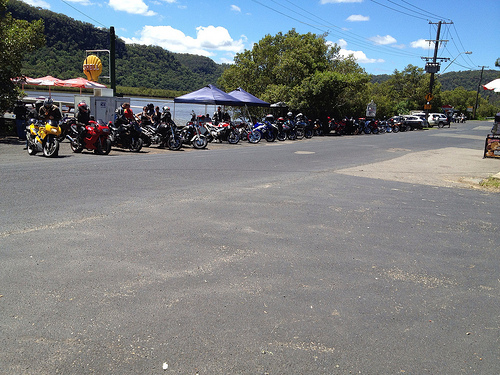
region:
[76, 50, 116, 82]
shell gas station shell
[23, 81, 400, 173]
row of motorcycles on the street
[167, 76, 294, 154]
blue tarps providing shade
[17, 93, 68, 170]
yellow motorcycle with a rider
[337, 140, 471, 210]
asphalt with two colors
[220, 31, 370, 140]
green tree behind a motorcycle line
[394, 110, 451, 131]
vehicles parked on the street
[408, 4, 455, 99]
telephone pole with power lines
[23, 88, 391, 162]
line of motorcycles on the street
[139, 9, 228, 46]
blue sky with fluffy white clouds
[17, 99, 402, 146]
Motorcycles line paved street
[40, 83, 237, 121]
Fresh water lake background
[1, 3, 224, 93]
Green foliage covered hills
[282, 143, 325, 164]
Sewage drain middle road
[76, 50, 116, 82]
Standard Shell gasoline symbol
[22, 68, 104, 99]
Orange white shade umbrellas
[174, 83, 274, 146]
Farmers Market purple umbrellas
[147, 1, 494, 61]
Bright blue sky few clouds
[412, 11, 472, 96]
Telephone wires transformer pole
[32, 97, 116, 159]
Riders just arrived still helmeted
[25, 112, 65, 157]
a motorbike is parked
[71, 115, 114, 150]
a motorbike is parked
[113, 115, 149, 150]
a motorbike is parked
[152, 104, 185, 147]
a motorbike is parked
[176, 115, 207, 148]
a motorbike is parked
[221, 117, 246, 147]
a motorbike is parked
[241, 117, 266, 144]
a motorbike is parked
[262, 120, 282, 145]
a motorbike is parked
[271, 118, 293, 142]
a motorbike is parked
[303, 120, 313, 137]
a motorbike is parked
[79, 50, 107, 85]
a yellow shell on the roof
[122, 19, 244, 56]
a white cloud in the sky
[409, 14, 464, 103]
a large power pole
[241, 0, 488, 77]
a set of power lines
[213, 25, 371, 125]
a large green tree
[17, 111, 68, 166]
a yellow motorcycle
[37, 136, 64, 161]
the wheel of a motorcycle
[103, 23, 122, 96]
a large wooden pole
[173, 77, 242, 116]
a blue tent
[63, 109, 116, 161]
a red motorcycle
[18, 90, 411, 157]
motorcycles are parked on the side of the road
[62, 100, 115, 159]
the rider is on the red motorcycle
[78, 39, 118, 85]
a yellow shell is hanging from a pole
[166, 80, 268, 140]
blue canopies are set up behind the cycles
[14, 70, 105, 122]
umbrellas are open in by the lake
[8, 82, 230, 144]
a lake is near the bikers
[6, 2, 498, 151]
hills covered with green vegetation are behind the lake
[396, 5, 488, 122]
utility poles are line the street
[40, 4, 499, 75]
the sky is blue with white clouds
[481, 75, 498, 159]
a person is sitting under an umbrella